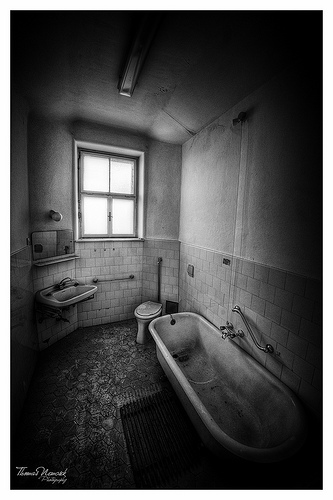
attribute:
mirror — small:
[29, 226, 76, 260]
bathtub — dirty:
[149, 312, 299, 454]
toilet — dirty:
[134, 299, 161, 343]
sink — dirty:
[38, 279, 98, 307]